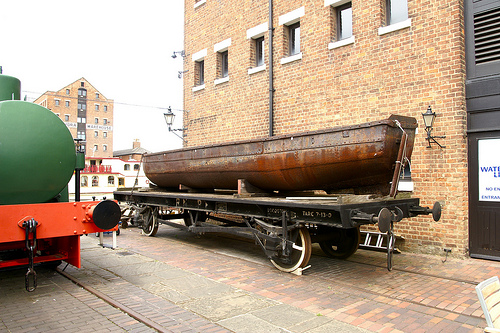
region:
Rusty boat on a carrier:
[140, 113, 418, 197]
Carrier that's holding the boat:
[114, 185, 445, 275]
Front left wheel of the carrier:
[134, 203, 161, 237]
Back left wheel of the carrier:
[260, 222, 312, 276]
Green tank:
[1, 72, 121, 287]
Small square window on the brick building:
[190, 42, 207, 94]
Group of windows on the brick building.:
[190, 1, 414, 93]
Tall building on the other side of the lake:
[32, 75, 114, 160]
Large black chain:
[18, 216, 40, 290]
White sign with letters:
[475, 132, 497, 204]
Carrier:
[111, 182, 443, 274]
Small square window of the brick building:
[188, 48, 208, 95]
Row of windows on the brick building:
[191, 2, 413, 89]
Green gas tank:
[0, 73, 124, 295]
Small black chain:
[15, 213, 46, 294]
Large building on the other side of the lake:
[38, 79, 115, 161]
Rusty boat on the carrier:
[111, 112, 418, 194]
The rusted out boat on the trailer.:
[132, 116, 414, 188]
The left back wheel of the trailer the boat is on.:
[259, 223, 310, 268]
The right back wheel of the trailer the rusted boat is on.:
[324, 220, 365, 262]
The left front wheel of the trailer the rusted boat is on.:
[137, 203, 167, 228]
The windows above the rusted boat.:
[188, 0, 420, 85]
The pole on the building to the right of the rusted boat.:
[269, 0, 274, 137]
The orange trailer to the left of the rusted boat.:
[0, 195, 112, 275]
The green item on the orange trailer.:
[3, 54, 88, 202]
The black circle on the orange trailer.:
[90, 195, 127, 236]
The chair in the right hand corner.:
[465, 270, 498, 331]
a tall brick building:
[32, 75, 113, 205]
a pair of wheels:
[260, 212, 361, 272]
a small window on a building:
[245, 22, 265, 69]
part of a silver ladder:
[355, 225, 405, 255]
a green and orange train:
[0, 70, 120, 292]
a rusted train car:
[113, 113, 445, 273]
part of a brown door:
[464, 122, 499, 262]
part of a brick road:
[38, 273, 471, 331]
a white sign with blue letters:
[474, 131, 499, 201]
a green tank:
[1, 73, 88, 210]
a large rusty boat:
[87, 98, 430, 267]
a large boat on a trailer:
[86, 107, 429, 282]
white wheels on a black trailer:
[238, 205, 343, 307]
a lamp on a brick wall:
[408, 102, 451, 158]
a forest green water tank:
[2, 92, 89, 205]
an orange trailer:
[0, 192, 122, 262]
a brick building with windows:
[37, 70, 131, 185]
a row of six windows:
[183, 0, 403, 90]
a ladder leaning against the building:
[335, 229, 417, 254]